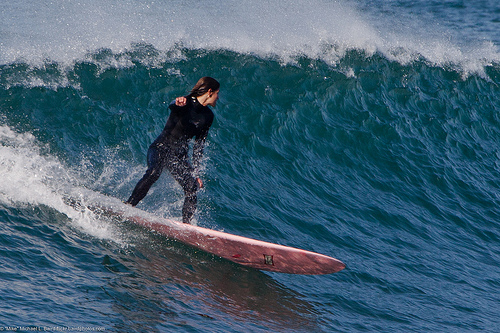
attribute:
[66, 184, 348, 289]
surfing board — white color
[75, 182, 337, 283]
surfboard — back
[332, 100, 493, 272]
water — turquoise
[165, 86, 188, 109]
hand — surfer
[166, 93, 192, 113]
arm — surfer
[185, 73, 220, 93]
hair — long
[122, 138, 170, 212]
leg — surfer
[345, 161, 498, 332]
water — blue color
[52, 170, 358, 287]
surfboard — blue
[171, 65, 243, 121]
head — surfer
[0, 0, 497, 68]
crest — white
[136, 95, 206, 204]
suit — body